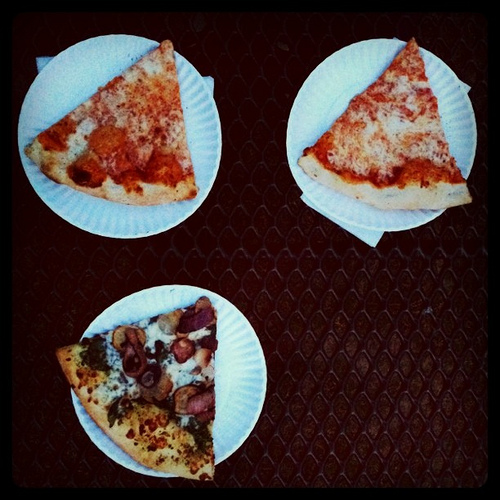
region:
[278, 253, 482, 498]
a red table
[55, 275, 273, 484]
white paper plate on the table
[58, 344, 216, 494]
crust on the pizza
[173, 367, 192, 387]
cheese on the pizza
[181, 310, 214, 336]
onion on the pizza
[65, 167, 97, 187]
burn on the pizza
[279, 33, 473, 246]
cheese pizza on paper plate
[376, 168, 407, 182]
sauce on the cheese pizza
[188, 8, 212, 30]
stain on the table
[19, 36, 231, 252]
white paper plate on the table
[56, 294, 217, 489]
slice of pizza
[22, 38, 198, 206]
slice of cheese pizza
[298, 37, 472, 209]
slice of cheese pizza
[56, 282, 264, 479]
slice of pizza in a paper plate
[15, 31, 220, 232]
slice of pizza on a paper plate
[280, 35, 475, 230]
slice of pizza on a paper plate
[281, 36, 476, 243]
plate of pizza sitting on a napkin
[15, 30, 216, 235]
plate of pizza sitting on a napkin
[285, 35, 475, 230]
slice of pizza in a paper plate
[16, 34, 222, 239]
a slice of pizza in a white paper plate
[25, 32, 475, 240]
two slices of cheese pizza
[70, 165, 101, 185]
brown bubble on the crust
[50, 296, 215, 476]
multiple toppings on the slice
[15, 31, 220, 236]
a white paper plate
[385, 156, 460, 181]
red pizza sauce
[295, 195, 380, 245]
a napkin under the plate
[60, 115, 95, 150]
cheese on the pizza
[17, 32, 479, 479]
three slices of pizza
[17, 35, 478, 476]
three paper plates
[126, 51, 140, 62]
crumbs on the plate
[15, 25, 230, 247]
The plate is round.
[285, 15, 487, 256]
The plate is round.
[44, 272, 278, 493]
The plate is round.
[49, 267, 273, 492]
The plate is in use.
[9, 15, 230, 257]
The plate is in use.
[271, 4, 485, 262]
The plate is in use.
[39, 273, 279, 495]
The plate is white.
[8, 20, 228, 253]
The plate is white.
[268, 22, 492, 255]
The plate is white.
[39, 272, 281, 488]
The plate is disposable.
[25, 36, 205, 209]
slice of pizza on plate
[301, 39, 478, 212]
slice of pizza on plate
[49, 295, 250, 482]
slice of pizza on plate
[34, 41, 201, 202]
slice of pizza on white plate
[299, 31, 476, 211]
slice of pizza on white plate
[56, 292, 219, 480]
slice of pizza on white plate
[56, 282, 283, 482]
white plate on table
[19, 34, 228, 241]
white plate on table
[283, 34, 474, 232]
white plate on table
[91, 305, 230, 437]
white cheese on pizza